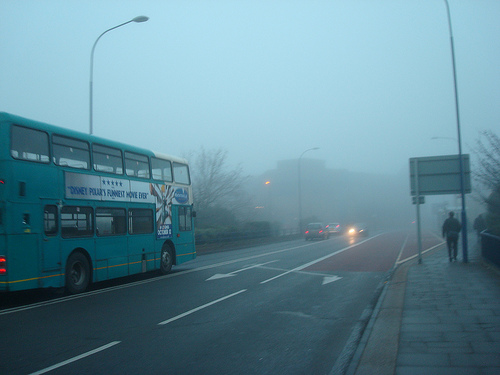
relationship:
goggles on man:
[447, 209, 454, 215] [440, 211, 463, 261]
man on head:
[440, 211, 463, 261] [446, 210, 455, 218]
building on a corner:
[191, 162, 413, 245] [246, 164, 419, 236]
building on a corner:
[269, 160, 403, 231] [327, 182, 360, 208]